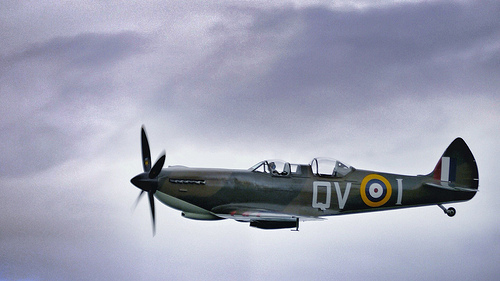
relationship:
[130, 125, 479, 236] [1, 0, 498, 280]
plane flying in sky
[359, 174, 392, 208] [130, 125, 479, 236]
bullseye on side of plane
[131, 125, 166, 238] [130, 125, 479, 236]
propeller helps fly plane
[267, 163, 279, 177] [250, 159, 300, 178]
pilot occupying cockpit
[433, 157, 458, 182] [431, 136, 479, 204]
stripes painted on tail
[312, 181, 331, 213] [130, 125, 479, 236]
q painted on side of plane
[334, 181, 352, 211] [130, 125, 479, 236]
v painted on side of plane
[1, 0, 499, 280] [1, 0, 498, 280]
clouds in sky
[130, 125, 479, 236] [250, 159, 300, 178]
plane has cockpit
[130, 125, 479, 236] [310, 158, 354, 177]
plane has cockpit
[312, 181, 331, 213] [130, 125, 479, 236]
q on plane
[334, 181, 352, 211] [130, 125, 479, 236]
v on plane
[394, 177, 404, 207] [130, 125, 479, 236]
i on plane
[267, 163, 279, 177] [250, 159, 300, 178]
pilot in cockpit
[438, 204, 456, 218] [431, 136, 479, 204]
landing gear under tail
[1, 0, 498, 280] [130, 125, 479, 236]
sky behind plane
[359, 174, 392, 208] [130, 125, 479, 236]
bullseye on plane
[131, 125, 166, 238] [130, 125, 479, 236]
propeller of plane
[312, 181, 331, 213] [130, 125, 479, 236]
q on side of plane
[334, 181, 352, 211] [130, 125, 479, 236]
v on side of plane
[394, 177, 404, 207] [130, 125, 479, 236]
i on side of plane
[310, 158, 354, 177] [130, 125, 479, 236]
cockpit of plane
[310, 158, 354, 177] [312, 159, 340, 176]
cockpit with cover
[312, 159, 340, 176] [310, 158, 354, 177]
cover over cockpit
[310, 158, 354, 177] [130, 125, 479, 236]
cockpit on plane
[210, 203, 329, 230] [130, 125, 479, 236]
wing of plane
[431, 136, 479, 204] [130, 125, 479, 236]
tail of plane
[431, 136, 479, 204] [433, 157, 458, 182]
tail with stripes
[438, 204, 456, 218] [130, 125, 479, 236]
landing gear of plane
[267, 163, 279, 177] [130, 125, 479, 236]
pilot of plane